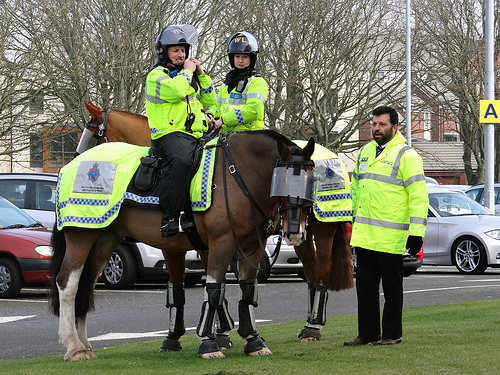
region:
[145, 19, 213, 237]
cop rides horse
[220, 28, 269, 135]
cop rides horse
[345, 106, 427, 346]
cop stands next to horse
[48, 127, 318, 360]
horse has cop on it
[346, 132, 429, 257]
jacket is worn by cop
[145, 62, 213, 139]
jacket is worn by cop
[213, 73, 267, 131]
jacket is worn by cop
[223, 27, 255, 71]
helmet is worn by cop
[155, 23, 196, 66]
helmet is worn by cop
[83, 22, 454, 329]
three people gathered together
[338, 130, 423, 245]
yellow safety jacket on person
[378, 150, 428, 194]
silver stripes on jacket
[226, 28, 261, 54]
black helmet on person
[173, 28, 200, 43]
clear visor on helmet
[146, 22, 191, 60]
black helmet on person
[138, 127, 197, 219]
black pants on rider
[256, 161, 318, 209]
clear visor on horse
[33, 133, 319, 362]
large brown horse standing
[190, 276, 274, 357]
padding on front of horse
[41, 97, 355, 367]
two horses wearing visors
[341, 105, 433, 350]
man wearing bright yellow coat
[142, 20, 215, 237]
man wearing bright yellow coat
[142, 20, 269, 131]
two people with helmets on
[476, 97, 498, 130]
yellow sign with the letter 'A'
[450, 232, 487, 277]
car tire with metal rim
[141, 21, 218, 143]
man adjusting his helmet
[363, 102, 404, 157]
man with a beard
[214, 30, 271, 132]
woman wearing a helmet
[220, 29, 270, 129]
woman wearing a bright yellow coat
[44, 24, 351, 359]
two police officers on horses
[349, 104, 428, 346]
officer with a beard, standing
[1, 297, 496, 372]
a grassy area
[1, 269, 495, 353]
a paved parking lot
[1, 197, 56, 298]
the red car on the left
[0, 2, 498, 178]
trees behind the parking lot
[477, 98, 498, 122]
yellow sign with letter A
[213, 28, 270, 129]
the female mounted officer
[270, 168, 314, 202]
face guard on the front horse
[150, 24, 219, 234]
officer on horse adjusting his helmet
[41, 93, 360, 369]
Two horses standing next to each other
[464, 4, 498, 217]
Silver pole with sign reading A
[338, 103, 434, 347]
Man wearing yellow raincoat and black pants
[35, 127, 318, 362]
Brown horse wearing visor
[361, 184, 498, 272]
Silver car parked in spot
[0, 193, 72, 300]
Front of parked red car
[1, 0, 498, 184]
A line of trees that have lost leaves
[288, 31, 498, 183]
White and brick building